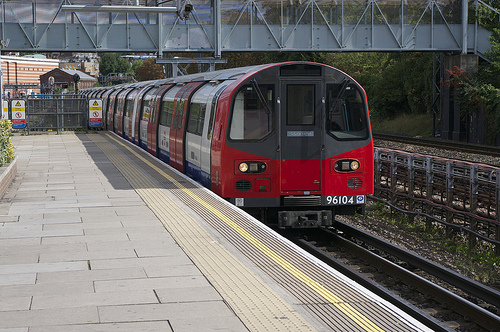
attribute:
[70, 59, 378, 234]
train — red, white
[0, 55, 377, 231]
train — moving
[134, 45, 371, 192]
train — red and white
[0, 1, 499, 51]
bridge — grey, metal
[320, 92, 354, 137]
driver seat — empty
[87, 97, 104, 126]
sign — red, white, yellow, and blue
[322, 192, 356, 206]
numbers — white